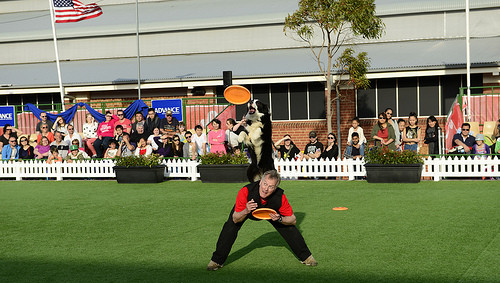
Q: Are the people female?
A: No, they are both male and female.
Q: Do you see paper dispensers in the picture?
A: No, there are no paper dispensers.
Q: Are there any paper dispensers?
A: No, there are no paper dispensers.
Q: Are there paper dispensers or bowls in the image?
A: No, there are no paper dispensers or bowls.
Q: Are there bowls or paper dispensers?
A: No, there are no paper dispensers or bowls.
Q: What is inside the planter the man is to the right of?
A: The plants are inside the planter.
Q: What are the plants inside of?
A: The plants are inside the planter.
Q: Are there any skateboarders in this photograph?
A: No, there are no skateboarders.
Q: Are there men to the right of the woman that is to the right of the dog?
A: Yes, there is a man to the right of the woman.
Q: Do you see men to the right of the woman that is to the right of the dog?
A: Yes, there is a man to the right of the woman.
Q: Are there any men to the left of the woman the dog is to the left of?
A: No, the man is to the right of the woman.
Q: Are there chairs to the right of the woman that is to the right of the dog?
A: No, there is a man to the right of the woman.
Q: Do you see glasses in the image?
A: No, there are no glasses.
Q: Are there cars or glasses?
A: No, there are no glasses or cars.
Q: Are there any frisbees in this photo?
A: Yes, there is a frisbee.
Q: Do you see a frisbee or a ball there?
A: Yes, there is a frisbee.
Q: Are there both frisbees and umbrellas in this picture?
A: No, there is a frisbee but no umbrellas.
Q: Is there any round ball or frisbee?
A: Yes, there is a round frisbee.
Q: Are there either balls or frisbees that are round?
A: Yes, the frisbee is round.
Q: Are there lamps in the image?
A: No, there are no lamps.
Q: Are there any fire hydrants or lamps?
A: No, there are no lamps or fire hydrants.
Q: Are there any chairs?
A: No, there are no chairs.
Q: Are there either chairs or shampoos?
A: No, there are no chairs or shampoos.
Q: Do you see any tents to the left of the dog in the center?
A: No, there is a planter to the left of the dog.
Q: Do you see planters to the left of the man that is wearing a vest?
A: Yes, there is a planter to the left of the man.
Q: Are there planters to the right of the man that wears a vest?
A: No, the planter is to the left of the man.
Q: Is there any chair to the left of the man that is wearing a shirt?
A: No, there is a planter to the left of the man.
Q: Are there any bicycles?
A: No, there are no bicycles.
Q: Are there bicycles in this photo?
A: No, there are no bicycles.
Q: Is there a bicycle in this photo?
A: No, there are no bicycles.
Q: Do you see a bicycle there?
A: No, there are no bicycles.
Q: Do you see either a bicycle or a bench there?
A: No, there are no bicycles or benches.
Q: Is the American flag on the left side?
A: Yes, the American flag is on the left of the image.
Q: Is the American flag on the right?
A: No, the American flag is on the left of the image.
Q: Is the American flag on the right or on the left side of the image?
A: The American flag is on the left of the image.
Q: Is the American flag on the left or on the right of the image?
A: The American flag is on the left of the image.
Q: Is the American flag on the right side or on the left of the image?
A: The American flag is on the left of the image.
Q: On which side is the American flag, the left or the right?
A: The American flag is on the left of the image.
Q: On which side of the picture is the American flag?
A: The American flag is on the left of the image.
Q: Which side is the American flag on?
A: The American flag is on the left of the image.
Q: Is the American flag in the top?
A: Yes, the American flag is in the top of the image.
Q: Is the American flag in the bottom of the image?
A: No, the American flag is in the top of the image.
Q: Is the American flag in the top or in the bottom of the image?
A: The American flag is in the top of the image.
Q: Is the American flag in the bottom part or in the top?
A: The American flag is in the top of the image.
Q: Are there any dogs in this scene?
A: Yes, there is a dog.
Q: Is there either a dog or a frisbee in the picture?
A: Yes, there is a dog.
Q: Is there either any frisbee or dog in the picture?
A: Yes, there is a dog.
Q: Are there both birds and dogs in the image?
A: No, there is a dog but no birds.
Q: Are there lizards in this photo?
A: No, there are no lizards.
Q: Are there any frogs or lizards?
A: No, there are no lizards or frogs.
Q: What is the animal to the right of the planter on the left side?
A: The animal is a dog.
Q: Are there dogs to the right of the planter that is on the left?
A: Yes, there is a dog to the right of the planter.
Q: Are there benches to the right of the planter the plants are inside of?
A: No, there is a dog to the right of the planter.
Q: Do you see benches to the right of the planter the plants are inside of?
A: No, there is a dog to the right of the planter.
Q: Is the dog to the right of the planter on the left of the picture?
A: Yes, the dog is to the right of the planter.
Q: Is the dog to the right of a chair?
A: No, the dog is to the right of the planter.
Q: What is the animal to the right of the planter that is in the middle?
A: The animal is a dog.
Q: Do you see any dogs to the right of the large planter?
A: Yes, there is a dog to the right of the planter.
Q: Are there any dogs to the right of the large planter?
A: Yes, there is a dog to the right of the planter.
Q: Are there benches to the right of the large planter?
A: No, there is a dog to the right of the planter.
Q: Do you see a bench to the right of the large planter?
A: No, there is a dog to the right of the planter.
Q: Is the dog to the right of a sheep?
A: No, the dog is to the right of the planter.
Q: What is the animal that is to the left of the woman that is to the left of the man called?
A: The animal is a dog.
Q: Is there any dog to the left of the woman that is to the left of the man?
A: Yes, there is a dog to the left of the woman.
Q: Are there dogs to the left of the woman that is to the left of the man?
A: Yes, there is a dog to the left of the woman.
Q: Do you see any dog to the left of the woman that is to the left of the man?
A: Yes, there is a dog to the left of the woman.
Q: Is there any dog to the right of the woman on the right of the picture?
A: No, the dog is to the left of the woman.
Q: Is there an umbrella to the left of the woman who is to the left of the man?
A: No, there is a dog to the left of the woman.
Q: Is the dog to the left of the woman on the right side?
A: Yes, the dog is to the left of the woman.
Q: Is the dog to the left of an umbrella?
A: No, the dog is to the left of the woman.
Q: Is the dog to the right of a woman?
A: No, the dog is to the left of a woman.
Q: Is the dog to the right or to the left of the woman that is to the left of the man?
A: The dog is to the left of the woman.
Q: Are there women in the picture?
A: Yes, there is a woman.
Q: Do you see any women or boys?
A: Yes, there is a woman.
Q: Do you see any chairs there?
A: No, there are no chairs.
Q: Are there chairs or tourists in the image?
A: No, there are no chairs or tourists.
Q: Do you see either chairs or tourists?
A: No, there are no chairs or tourists.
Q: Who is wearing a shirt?
A: The woman is wearing a shirt.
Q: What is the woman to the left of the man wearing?
A: The woman is wearing a shirt.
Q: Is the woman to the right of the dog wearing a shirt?
A: Yes, the woman is wearing a shirt.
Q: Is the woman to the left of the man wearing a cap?
A: No, the woman is wearing a shirt.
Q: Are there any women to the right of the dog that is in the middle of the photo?
A: Yes, there is a woman to the right of the dog.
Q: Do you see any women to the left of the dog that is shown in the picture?
A: No, the woman is to the right of the dog.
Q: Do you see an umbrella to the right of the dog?
A: No, there is a woman to the right of the dog.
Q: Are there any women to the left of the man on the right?
A: Yes, there is a woman to the left of the man.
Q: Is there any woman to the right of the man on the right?
A: No, the woman is to the left of the man.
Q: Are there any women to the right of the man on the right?
A: No, the woman is to the left of the man.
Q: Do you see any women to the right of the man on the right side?
A: No, the woman is to the left of the man.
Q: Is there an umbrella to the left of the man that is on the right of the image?
A: No, there is a woman to the left of the man.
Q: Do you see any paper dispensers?
A: No, there are no paper dispensers.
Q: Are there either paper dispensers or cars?
A: No, there are no paper dispensers or cars.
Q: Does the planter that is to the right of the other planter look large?
A: Yes, the planter is large.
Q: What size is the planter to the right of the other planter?
A: The planter is large.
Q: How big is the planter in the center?
A: The planter is large.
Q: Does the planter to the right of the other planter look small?
A: No, the planter is large.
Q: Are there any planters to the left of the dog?
A: Yes, there is a planter to the left of the dog.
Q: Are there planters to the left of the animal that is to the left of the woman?
A: Yes, there is a planter to the left of the dog.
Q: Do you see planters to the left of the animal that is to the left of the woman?
A: Yes, there is a planter to the left of the dog.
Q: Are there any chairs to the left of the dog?
A: No, there is a planter to the left of the dog.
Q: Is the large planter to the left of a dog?
A: Yes, the planter is to the left of a dog.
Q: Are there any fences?
A: Yes, there is a fence.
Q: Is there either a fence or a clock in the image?
A: Yes, there is a fence.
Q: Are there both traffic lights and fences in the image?
A: No, there is a fence but no traffic lights.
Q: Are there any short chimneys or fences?
A: Yes, there is a short fence.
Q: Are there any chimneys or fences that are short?
A: Yes, the fence is short.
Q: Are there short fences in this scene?
A: Yes, there is a short fence.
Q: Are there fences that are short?
A: Yes, there is a fence that is short.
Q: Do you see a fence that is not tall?
A: Yes, there is a short fence.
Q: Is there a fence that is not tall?
A: Yes, there is a short fence.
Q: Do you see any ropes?
A: No, there are no ropes.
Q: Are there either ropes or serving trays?
A: No, there are no ropes or serving trays.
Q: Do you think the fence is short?
A: Yes, the fence is short.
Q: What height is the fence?
A: The fence is short.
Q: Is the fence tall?
A: No, the fence is short.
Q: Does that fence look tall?
A: No, the fence is short.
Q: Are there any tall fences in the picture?
A: No, there is a fence but it is short.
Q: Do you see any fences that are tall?
A: No, there is a fence but it is short.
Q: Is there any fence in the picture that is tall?
A: No, there is a fence but it is short.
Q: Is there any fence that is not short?
A: No, there is a fence but it is short.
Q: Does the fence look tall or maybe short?
A: The fence is short.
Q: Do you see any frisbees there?
A: Yes, there is a frisbee.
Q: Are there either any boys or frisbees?
A: Yes, there is a frisbee.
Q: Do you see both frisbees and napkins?
A: No, there is a frisbee but no napkins.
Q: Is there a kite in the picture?
A: No, there are no kites.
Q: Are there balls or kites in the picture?
A: No, there are no kites or balls.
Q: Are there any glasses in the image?
A: No, there are no glasses.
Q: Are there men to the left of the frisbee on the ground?
A: Yes, there is a man to the left of the frisbee.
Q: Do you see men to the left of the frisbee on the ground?
A: Yes, there is a man to the left of the frisbee.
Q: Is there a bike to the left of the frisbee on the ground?
A: No, there is a man to the left of the frisbee.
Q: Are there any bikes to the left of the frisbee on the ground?
A: No, there is a man to the left of the frisbee.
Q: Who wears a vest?
A: The man wears a vest.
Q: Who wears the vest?
A: The man wears a vest.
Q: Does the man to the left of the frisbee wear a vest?
A: Yes, the man wears a vest.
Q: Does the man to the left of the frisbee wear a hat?
A: No, the man wears a vest.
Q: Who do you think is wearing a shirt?
A: The man is wearing a shirt.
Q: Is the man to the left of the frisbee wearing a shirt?
A: Yes, the man is wearing a shirt.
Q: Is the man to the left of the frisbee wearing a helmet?
A: No, the man is wearing a shirt.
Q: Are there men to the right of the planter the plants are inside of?
A: Yes, there is a man to the right of the planter.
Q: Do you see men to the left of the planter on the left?
A: No, the man is to the right of the planter.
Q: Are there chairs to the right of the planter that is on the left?
A: No, there is a man to the right of the planter.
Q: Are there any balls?
A: No, there are no balls.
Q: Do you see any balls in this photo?
A: No, there are no balls.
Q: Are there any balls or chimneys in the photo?
A: No, there are no balls or chimneys.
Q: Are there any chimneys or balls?
A: No, there are no balls or chimneys.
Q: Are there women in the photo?
A: Yes, there is a woman.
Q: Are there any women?
A: Yes, there is a woman.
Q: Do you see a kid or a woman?
A: Yes, there is a woman.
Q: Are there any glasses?
A: No, there are no glasses.